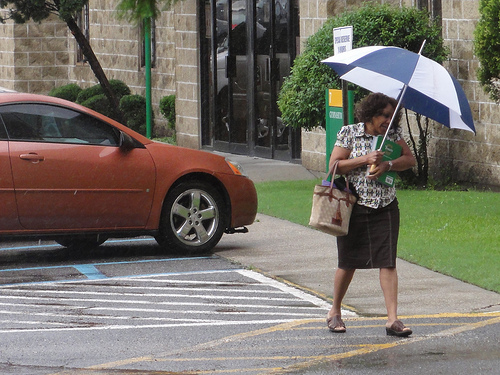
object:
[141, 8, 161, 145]
green pole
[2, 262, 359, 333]
lines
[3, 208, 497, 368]
lot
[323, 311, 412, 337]
shoes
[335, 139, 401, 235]
blouse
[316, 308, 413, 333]
sandals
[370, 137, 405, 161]
books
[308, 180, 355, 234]
bag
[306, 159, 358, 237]
purse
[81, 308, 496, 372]
lines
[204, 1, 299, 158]
black door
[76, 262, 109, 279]
line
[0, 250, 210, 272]
line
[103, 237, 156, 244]
line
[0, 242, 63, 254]
line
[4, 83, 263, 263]
compact car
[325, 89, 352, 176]
sign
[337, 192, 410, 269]
skirt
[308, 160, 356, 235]
handbag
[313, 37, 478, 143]
umbrella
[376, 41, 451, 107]
stripes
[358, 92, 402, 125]
hair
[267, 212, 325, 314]
sidewalk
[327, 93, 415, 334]
woman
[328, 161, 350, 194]
straps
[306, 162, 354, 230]
tote bag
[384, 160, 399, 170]
watch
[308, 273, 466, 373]
sidewalk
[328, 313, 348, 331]
shoe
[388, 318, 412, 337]
shoe